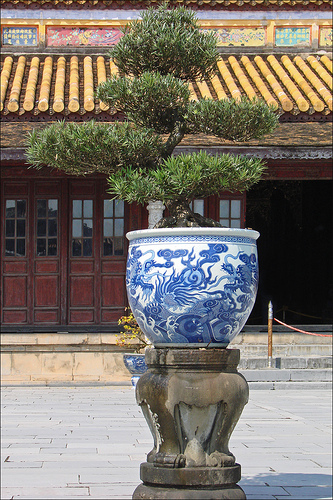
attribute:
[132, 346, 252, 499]
pedestal — cement, concrete, stone, chipped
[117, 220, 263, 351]
planter — white, blue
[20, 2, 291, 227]
bonsai — old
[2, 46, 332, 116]
sticks — bamboo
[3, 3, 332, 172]
roof — yellow, bamboo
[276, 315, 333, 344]
rope — velvet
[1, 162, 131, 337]
wall — wooden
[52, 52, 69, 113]
rod — wood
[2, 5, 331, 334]
building — asian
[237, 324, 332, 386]
stairs — cement, grey, small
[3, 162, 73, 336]
door — red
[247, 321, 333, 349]
stone — gray